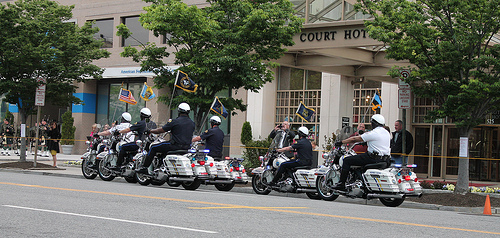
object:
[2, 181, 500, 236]
strip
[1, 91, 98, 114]
stripe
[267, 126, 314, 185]
police officer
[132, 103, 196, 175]
police officer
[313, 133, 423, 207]
motorcycle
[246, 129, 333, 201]
motorcycle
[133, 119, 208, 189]
motorcycle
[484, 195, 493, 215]
cone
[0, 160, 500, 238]
road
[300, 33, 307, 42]
letters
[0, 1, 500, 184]
building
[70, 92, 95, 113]
paint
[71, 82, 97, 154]
pillar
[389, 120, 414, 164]
guy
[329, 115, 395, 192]
cops